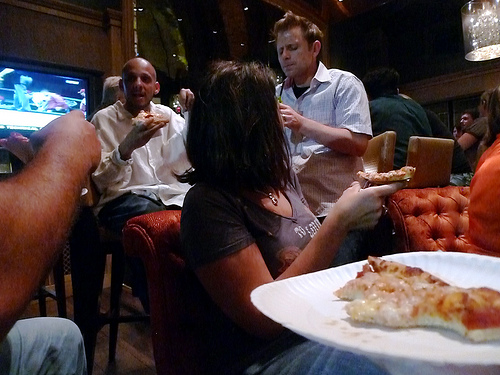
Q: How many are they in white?
A: 2.